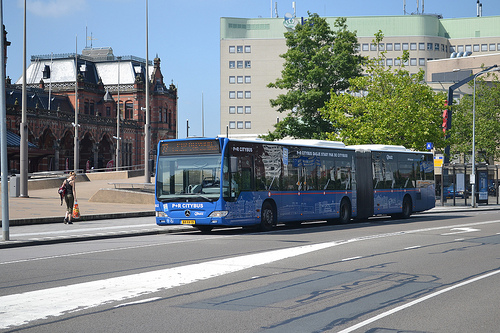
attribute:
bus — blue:
[155, 136, 357, 231]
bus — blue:
[346, 142, 437, 217]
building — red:
[16, 29, 213, 209]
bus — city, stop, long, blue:
[150, 133, 444, 234]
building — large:
[217, 15, 498, 167]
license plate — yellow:
[175, 216, 200, 230]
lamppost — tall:
[441, 57, 498, 194]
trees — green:
[257, 9, 499, 159]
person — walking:
[55, 168, 82, 225]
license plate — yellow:
[179, 220, 198, 227]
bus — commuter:
[140, 127, 446, 232]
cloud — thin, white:
[11, 0, 83, 25]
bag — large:
[56, 165, 79, 225]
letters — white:
[164, 196, 212, 212]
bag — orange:
[71, 200, 81, 218]